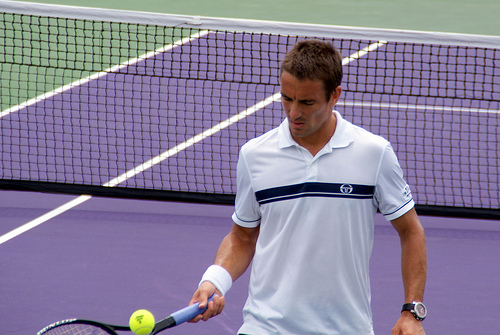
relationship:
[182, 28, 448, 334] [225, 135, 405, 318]
man wearing shirt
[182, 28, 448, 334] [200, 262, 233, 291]
man wearing wristband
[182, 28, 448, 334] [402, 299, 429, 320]
man wearing watch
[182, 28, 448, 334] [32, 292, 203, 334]
man holding racket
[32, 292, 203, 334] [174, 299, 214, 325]
racket has tape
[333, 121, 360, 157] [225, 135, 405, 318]
collar of a shirt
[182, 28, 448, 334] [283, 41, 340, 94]
man has hair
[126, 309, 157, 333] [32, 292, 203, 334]
tennis ball bouncing on racket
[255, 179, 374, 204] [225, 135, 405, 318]
stripe across shirt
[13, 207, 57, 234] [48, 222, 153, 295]
line painted on court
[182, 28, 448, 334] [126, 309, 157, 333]
man looking at tennis ball